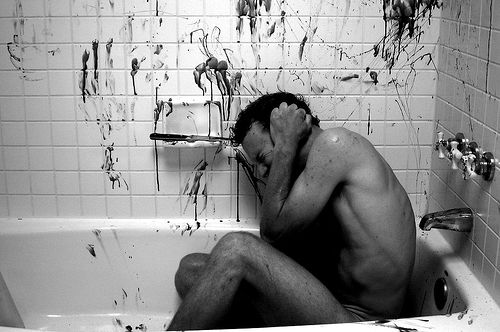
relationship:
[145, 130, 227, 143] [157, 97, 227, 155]
knife in soap dish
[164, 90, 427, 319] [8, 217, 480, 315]
man naked in a tub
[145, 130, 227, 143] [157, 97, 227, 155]
knife on a soap dish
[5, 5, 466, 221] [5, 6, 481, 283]
blood on walls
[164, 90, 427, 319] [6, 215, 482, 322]
man in a bathtub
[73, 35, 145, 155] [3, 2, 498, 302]
prints on wall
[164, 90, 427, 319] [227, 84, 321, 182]
man holding h head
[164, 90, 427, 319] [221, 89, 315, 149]
man with hair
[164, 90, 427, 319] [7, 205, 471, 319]
man in bathtub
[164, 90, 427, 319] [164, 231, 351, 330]
man with legs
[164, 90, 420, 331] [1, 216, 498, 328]
man in tub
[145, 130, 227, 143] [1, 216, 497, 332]
knife in tub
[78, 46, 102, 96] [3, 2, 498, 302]
blood spatter on wall